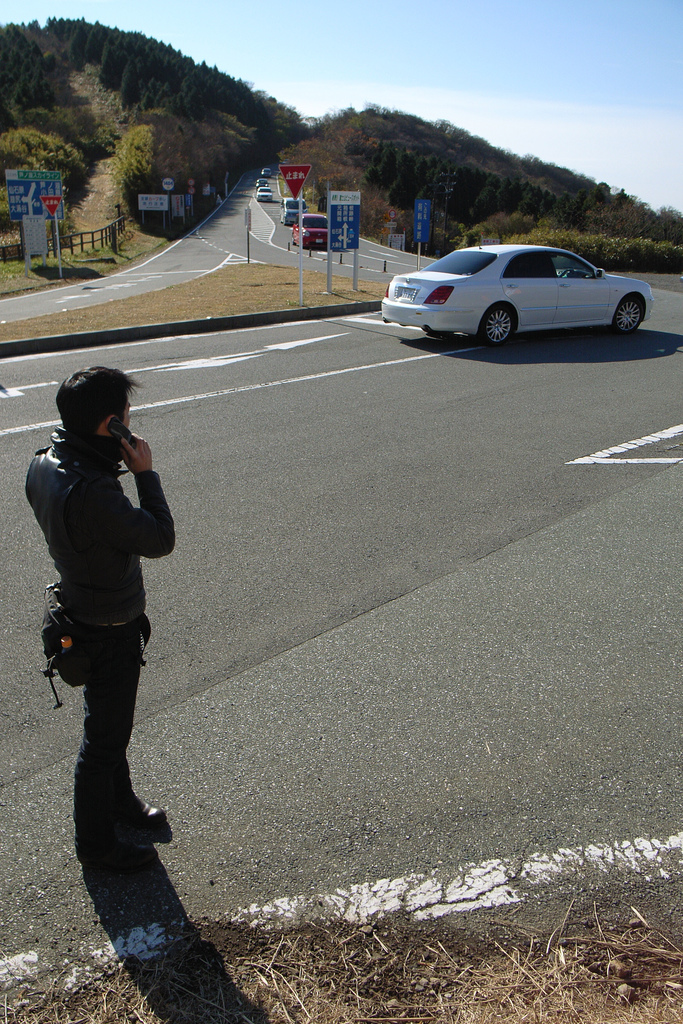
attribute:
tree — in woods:
[111, 122, 192, 236]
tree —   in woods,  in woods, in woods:
[116, 117, 195, 236]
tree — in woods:
[116, 117, 197, 226]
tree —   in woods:
[121, 105, 195, 224]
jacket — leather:
[29, 426, 179, 623]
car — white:
[379, 243, 655, 346]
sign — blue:
[412, 195, 430, 248]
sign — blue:
[332, 187, 360, 255]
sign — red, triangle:
[278, 164, 312, 198]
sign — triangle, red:
[40, 194, 64, 215]